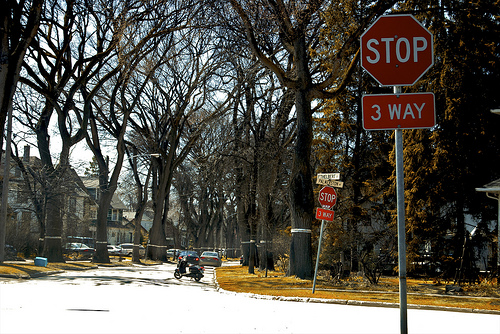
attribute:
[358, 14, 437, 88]
stop sign — red, white, octagon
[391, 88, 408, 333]
post — metal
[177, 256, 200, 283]
scooter — parked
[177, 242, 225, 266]
cars — traveling, parked, running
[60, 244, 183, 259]
cars — parked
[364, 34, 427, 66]
text — white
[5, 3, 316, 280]
trees — big, large, bare, plenty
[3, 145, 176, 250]
houses — lined, large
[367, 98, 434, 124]
3 way — red, rectangular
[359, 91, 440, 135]
sign — red, white, stop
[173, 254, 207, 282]
motorcycle — parked, black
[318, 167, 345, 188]
street sign — white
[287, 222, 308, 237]
band — white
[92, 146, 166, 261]
street light — off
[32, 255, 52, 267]
box — blue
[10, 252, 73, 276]
grass — golden